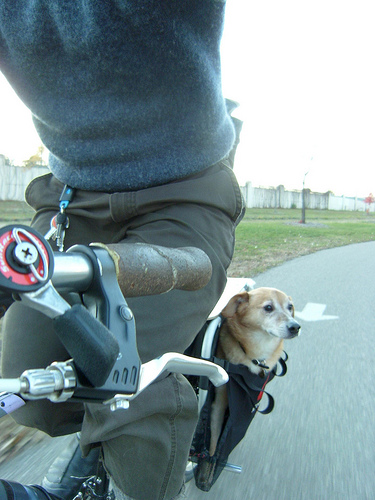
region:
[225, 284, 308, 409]
dog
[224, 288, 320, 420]
dog looking at road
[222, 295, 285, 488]
dog in a bag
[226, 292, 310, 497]
dog in a black bag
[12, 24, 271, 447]
person a motorcycle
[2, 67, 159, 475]
person riding a motorcycle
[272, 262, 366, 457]
street with a white arrow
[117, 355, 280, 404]
silver brake on motorcycle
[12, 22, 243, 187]
grey sweater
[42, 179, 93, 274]
keys attached to person's waist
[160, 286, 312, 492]
dog inside of bag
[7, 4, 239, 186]
person wearing dark blue sweater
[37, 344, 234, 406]
left breaks on bike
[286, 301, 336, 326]
white arrow painted on street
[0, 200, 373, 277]
green grass next to street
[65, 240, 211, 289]
left handle on bike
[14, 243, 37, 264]
Phillips screw on bike handle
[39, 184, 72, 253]
keys attached to person's belt loop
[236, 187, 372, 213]
white fence next to grass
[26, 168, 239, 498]
person wearing black pants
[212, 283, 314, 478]
dog in bag on bike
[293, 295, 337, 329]
white arrow on pavement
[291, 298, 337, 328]
white arrow pointing up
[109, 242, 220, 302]
worn out handle on motorcycle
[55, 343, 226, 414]
grip on motorcycle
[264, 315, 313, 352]
black nose on dog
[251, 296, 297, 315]
dark eyes on dog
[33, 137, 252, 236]
person's dark colored pants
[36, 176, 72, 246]
keys hanging from person's pants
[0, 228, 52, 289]
red background of hardware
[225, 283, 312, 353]
the dog is brown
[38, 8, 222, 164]
the sweater is grey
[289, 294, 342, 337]
the arrow is white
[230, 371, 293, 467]
the bag is black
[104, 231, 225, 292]
the handle is grey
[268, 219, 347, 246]
the grass is green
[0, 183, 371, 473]
the photo was taken during the day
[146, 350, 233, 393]
the brakes are silver in color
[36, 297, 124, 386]
the gear changer has black end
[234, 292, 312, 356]
the dog is enjoying the ride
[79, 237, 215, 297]
The handle of a bike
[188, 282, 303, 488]
A dog with floppy ears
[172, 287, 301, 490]
A dog in a bag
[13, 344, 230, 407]
The brake handle of a bike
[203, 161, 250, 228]
The left pocket of the person's pants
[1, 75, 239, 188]
A blue-gray sweater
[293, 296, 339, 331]
A white arrow on the road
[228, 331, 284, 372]
The dog's collar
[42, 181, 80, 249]
A set of keys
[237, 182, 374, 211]
A long wooden fence